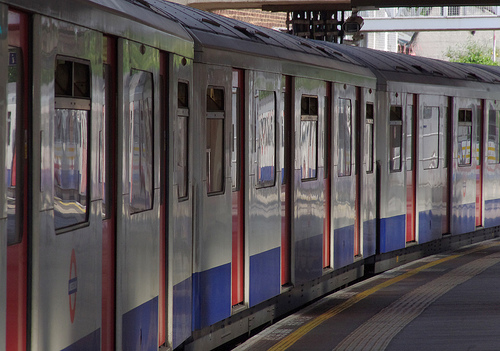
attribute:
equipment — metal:
[286, 6, 364, 44]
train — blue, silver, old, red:
[8, 3, 498, 346]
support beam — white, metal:
[290, 21, 499, 28]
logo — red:
[66, 250, 83, 326]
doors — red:
[7, 10, 499, 350]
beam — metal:
[264, 2, 499, 45]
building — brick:
[222, 0, 288, 30]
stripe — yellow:
[267, 235, 497, 349]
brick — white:
[377, 310, 401, 340]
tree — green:
[448, 31, 499, 67]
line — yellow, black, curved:
[235, 180, 496, 350]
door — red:
[228, 70, 247, 310]